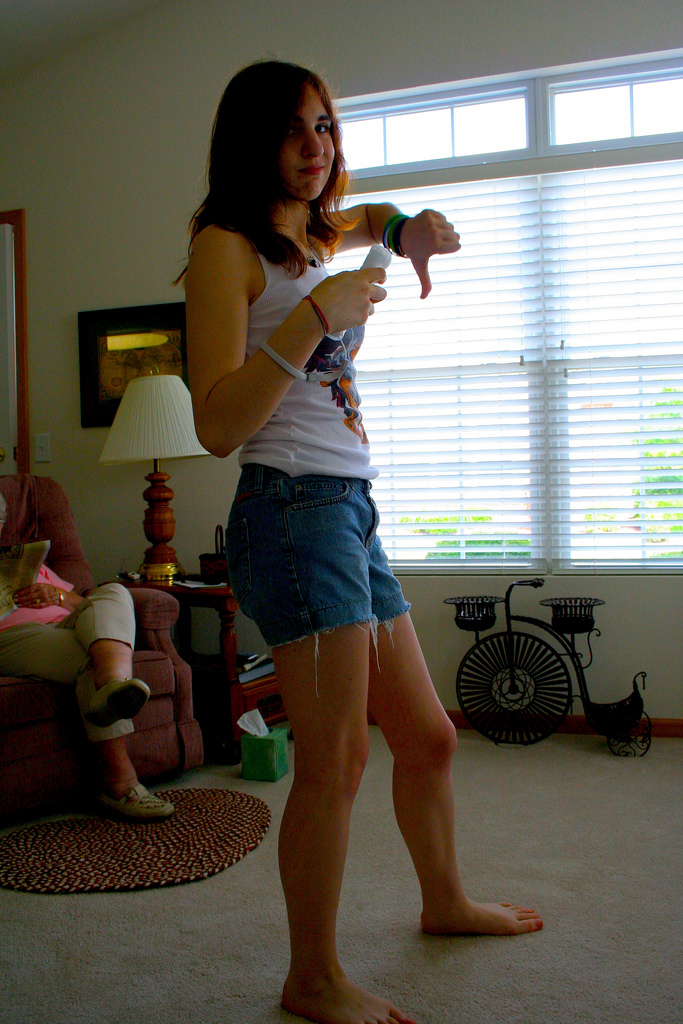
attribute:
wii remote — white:
[326, 230, 398, 359]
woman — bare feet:
[155, 39, 559, 1015]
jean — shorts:
[212, 468, 413, 649]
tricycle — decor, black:
[436, 565, 659, 761]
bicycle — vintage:
[441, 568, 667, 764]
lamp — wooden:
[90, 366, 216, 567]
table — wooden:
[125, 570, 246, 738]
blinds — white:
[339, 41, 681, 584]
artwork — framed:
[68, 297, 199, 436]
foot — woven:
[90, 764, 176, 823]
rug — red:
[9, 779, 274, 898]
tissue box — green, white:
[232, 707, 291, 781]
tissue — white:
[230, 697, 272, 736]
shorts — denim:
[214, 453, 415, 651]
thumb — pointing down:
[412, 250, 434, 299]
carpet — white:
[9, 691, 659, 1005]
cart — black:
[439, 567, 652, 760]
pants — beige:
[14, 577, 138, 742]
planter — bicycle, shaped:
[442, 569, 655, 757]